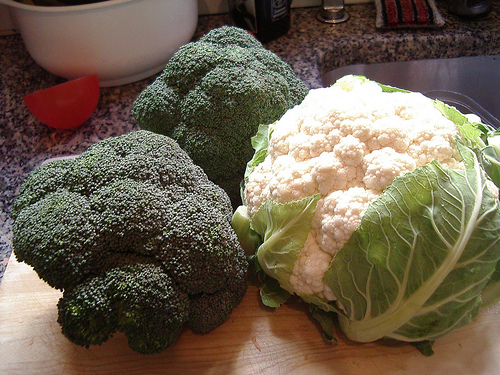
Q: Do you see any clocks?
A: No, there are no clocks.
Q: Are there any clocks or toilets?
A: No, there are no clocks or toilets.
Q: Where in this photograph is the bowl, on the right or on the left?
A: The bowl is on the left of the image.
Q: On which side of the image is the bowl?
A: The bowl is on the left of the image.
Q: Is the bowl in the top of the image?
A: Yes, the bowl is in the top of the image.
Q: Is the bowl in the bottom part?
A: No, the bowl is in the top of the image.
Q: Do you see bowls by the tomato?
A: Yes, there is a bowl by the tomato.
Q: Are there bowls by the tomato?
A: Yes, there is a bowl by the tomato.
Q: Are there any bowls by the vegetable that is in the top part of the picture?
A: Yes, there is a bowl by the tomato.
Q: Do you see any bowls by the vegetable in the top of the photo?
A: Yes, there is a bowl by the tomato.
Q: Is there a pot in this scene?
A: No, there are no pots.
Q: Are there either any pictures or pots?
A: No, there are no pots or pictures.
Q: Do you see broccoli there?
A: Yes, there is broccoli.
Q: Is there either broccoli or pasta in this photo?
A: Yes, there is broccoli.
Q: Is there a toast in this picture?
A: No, there are no toasts.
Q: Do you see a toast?
A: No, there are no toasts.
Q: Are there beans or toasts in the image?
A: No, there are no toasts or beans.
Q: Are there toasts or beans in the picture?
A: No, there are no toasts or beans.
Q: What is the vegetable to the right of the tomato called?
A: The vegetable is broccoli.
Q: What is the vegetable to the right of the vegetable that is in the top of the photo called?
A: The vegetable is broccoli.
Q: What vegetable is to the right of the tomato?
A: The vegetable is broccoli.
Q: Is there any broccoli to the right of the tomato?
A: Yes, there is broccoli to the right of the tomato.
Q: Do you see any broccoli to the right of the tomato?
A: Yes, there is broccoli to the right of the tomato.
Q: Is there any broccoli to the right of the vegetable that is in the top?
A: Yes, there is broccoli to the right of the tomato.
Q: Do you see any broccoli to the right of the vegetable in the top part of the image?
A: Yes, there is broccoli to the right of the tomato.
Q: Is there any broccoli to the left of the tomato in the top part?
A: No, the broccoli is to the right of the tomato.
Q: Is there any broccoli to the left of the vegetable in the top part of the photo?
A: No, the broccoli is to the right of the tomato.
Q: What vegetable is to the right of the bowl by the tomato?
A: The vegetable is broccoli.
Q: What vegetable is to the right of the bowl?
A: The vegetable is broccoli.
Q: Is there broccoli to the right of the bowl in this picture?
A: Yes, there is broccoli to the right of the bowl.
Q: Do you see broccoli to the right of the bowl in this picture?
A: Yes, there is broccoli to the right of the bowl.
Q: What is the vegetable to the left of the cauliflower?
A: The vegetable is broccoli.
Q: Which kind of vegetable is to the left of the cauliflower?
A: The vegetable is broccoli.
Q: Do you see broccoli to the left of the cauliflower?
A: Yes, there is broccoli to the left of the cauliflower.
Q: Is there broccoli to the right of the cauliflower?
A: No, the broccoli is to the left of the cauliflower.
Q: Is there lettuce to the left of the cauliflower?
A: No, there is broccoli to the left of the cauliflower.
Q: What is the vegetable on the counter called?
A: The vegetable is broccoli.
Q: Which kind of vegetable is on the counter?
A: The vegetable is broccoli.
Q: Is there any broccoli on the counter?
A: Yes, there is broccoli on the counter.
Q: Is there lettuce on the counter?
A: No, there is broccoli on the counter.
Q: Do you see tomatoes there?
A: Yes, there is a tomato.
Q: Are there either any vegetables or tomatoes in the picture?
A: Yes, there is a tomato.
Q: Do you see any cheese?
A: No, there is no cheese.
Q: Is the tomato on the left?
A: Yes, the tomato is on the left of the image.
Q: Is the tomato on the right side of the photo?
A: No, the tomato is on the left of the image.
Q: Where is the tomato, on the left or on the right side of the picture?
A: The tomato is on the left of the image.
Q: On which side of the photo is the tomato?
A: The tomato is on the left of the image.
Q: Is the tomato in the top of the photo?
A: Yes, the tomato is in the top of the image.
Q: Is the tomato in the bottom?
A: No, the tomato is in the top of the image.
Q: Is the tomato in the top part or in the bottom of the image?
A: The tomato is in the top of the image.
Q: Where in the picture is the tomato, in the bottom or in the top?
A: The tomato is in the top of the image.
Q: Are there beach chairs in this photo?
A: No, there are no beach chairs.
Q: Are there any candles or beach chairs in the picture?
A: No, there are no beach chairs or candles.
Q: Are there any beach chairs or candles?
A: No, there are no beach chairs or candles.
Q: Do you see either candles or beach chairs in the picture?
A: No, there are no beach chairs or candles.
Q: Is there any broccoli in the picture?
A: Yes, there is broccoli.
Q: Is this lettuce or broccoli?
A: This is broccoli.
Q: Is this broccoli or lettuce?
A: This is broccoli.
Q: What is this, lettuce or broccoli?
A: This is broccoli.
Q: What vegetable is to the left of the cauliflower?
A: The vegetable is broccoli.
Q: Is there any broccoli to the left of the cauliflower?
A: Yes, there is broccoli to the left of the cauliflower.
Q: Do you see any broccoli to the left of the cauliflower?
A: Yes, there is broccoli to the left of the cauliflower.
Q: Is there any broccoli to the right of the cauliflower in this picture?
A: No, the broccoli is to the left of the cauliflower.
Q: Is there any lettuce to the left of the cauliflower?
A: No, there is broccoli to the left of the cauliflower.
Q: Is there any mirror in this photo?
A: No, there are no mirrors.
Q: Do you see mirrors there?
A: No, there are no mirrors.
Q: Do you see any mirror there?
A: No, there are no mirrors.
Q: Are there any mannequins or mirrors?
A: No, there are no mirrors or mannequins.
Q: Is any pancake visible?
A: No, there are no pancakes.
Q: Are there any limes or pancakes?
A: No, there are no pancakes or limes.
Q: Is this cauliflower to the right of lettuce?
A: No, the cauliflower is to the right of the broccoli.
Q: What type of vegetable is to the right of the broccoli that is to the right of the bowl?
A: The vegetable is cauliflower.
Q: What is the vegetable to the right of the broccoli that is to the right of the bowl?
A: The vegetable is cauliflower.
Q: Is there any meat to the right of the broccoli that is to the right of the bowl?
A: No, there is cauliflower to the right of the broccoli.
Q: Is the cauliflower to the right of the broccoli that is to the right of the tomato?
A: Yes, the cauliflower is to the right of the broccoli.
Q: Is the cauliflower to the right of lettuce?
A: No, the cauliflower is to the right of the broccoli.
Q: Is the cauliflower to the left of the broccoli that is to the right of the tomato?
A: No, the cauliflower is to the right of the broccoli.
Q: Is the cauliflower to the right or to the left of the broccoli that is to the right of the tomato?
A: The cauliflower is to the right of the broccoli.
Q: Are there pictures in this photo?
A: No, there are no pictures.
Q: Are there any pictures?
A: No, there are no pictures.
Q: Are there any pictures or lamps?
A: No, there are no pictures or lamps.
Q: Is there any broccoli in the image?
A: Yes, there is broccoli.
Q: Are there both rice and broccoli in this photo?
A: No, there is broccoli but no rice.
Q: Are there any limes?
A: No, there are no limes.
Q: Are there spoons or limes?
A: No, there are no limes or spoons.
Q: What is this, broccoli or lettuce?
A: This is broccoli.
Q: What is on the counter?
A: The broccoli is on the counter.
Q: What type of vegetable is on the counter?
A: The vegetable is broccoli.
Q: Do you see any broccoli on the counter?
A: Yes, there is broccoli on the counter.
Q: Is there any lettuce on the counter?
A: No, there is broccoli on the counter.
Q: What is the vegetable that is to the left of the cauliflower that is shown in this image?
A: The vegetable is broccoli.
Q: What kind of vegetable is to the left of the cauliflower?
A: The vegetable is broccoli.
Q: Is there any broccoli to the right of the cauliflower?
A: No, the broccoli is to the left of the cauliflower.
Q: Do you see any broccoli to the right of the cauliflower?
A: No, the broccoli is to the left of the cauliflower.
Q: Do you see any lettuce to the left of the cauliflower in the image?
A: No, there is broccoli to the left of the cauliflower.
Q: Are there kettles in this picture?
A: No, there are no kettles.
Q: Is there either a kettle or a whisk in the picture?
A: No, there are no kettles or whisks.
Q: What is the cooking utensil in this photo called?
A: The cooking utensil is a cutting board.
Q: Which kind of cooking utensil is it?
A: The cooking utensil is a cutting board.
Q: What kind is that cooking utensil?
A: This is a cutting board.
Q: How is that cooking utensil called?
A: This is a cutting board.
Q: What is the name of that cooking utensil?
A: This is a cutting board.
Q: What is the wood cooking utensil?
A: The cooking utensil is a cutting board.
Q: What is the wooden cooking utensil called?
A: The cooking utensil is a cutting board.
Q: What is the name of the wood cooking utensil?
A: The cooking utensil is a cutting board.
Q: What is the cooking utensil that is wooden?
A: The cooking utensil is a cutting board.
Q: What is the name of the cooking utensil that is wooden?
A: The cooking utensil is a cutting board.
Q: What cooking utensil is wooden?
A: The cooking utensil is a cutting board.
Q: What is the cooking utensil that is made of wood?
A: The cooking utensil is a cutting board.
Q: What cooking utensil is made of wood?
A: The cooking utensil is a cutting board.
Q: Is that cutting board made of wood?
A: Yes, the cutting board is made of wood.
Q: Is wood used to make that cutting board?
A: Yes, the cutting board is made of wood.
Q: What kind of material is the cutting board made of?
A: The cutting board is made of wood.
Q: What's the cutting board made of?
A: The cutting board is made of wood.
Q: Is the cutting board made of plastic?
A: No, the cutting board is made of wood.